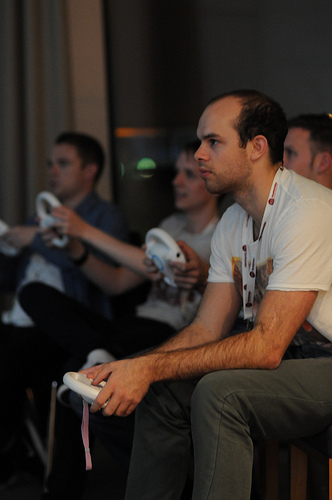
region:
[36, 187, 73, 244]
white controller in person's hand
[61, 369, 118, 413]
white controller in person's hand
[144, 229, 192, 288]
white controller in person's hand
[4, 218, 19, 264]
white controller in person's hand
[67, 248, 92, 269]
black watch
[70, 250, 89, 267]
black watch worn by young man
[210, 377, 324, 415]
gray pants worn by man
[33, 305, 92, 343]
black pants worn by man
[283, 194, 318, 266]
white shirt worn by man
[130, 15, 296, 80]
gray interior wall in room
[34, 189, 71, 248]
white wii steering wheel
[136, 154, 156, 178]
dim green light in background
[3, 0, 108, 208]
thick tan curtain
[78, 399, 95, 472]
pink strap hanging from wii steering wheel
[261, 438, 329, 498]
legs from brown wooden chair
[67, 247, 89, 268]
black band on woman's wrist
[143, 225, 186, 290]
steering wheel with blue circle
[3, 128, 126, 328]
man in blue shirt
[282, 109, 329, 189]
head of man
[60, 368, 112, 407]
wii wheel with pink cord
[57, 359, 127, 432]
wheel for wii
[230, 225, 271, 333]
tag holder for compition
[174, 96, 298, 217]
the man has dark hair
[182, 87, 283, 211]
it looks like the man is balding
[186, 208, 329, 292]
the man is wearing a short sleeved shirt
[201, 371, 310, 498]
the man is wearin jeans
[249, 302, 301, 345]
the man has a scare on his arm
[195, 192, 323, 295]
the man is wearing a white shirt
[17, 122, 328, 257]
there are 4 people playin against each other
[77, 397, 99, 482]
the controler wristband is pink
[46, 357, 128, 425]
a wii driving control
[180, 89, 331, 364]
a focused gamer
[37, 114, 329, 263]
four people racing in a video game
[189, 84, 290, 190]
a man needing to shave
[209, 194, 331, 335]
a white t shirt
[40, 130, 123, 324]
a man with a blue shirt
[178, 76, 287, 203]
man with a receeding hair line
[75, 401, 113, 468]
a pink strap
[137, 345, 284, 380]
hairy arms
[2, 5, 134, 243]
curtains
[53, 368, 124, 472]
Nintendo Wii steering wheel controller.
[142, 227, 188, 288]
Nintendo Wii steering wheel controller.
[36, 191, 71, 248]
Nintendo Wii steering wheel controller.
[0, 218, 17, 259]
Nintendo Wii steering wheel controller.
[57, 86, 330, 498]
Man playing video game.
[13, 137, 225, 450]
Person playing video game.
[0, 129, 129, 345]
Person paying video game.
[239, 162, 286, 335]
Lanyard with admission ticket.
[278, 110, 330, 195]
Person watching video game being played.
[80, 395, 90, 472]
Pink string on video game controller.